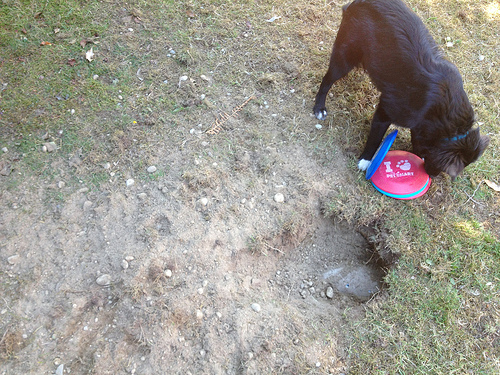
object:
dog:
[311, 0, 488, 182]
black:
[382, 45, 415, 76]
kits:
[371, 149, 430, 196]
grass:
[6, 14, 42, 46]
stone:
[273, 192, 285, 202]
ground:
[196, 100, 258, 162]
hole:
[288, 215, 384, 307]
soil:
[238, 45, 265, 77]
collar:
[442, 130, 469, 141]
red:
[389, 181, 413, 191]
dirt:
[98, 206, 145, 267]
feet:
[356, 158, 370, 171]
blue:
[384, 139, 391, 146]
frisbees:
[372, 177, 429, 199]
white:
[362, 161, 368, 165]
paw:
[313, 108, 328, 121]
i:
[383, 161, 393, 173]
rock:
[325, 285, 334, 299]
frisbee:
[365, 129, 399, 181]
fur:
[355, 21, 378, 48]